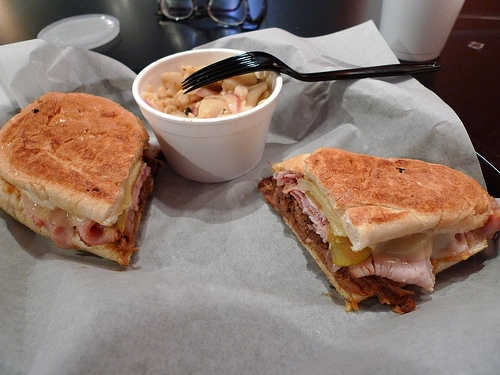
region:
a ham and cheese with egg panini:
[265, 148, 494, 325]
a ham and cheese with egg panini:
[2, 94, 159, 291]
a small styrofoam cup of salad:
[132, 43, 291, 191]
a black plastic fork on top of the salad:
[179, 43, 465, 98]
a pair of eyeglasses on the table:
[153, 0, 275, 34]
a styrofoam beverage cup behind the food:
[372, 0, 467, 71]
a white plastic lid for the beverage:
[26, 12, 130, 54]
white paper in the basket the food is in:
[361, 86, 478, 156]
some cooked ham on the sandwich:
[357, 253, 442, 295]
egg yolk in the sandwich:
[327, 239, 368, 269]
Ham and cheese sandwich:
[267, 151, 499, 323]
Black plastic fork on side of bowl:
[173, 50, 498, 115]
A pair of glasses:
[151, 0, 283, 27]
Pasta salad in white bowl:
[139, 48, 269, 135]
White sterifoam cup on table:
[147, 111, 279, 188]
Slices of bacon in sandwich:
[312, 260, 420, 325]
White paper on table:
[22, 279, 369, 374]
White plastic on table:
[27, 10, 127, 55]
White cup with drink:
[375, 0, 490, 80]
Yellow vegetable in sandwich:
[321, 227, 376, 278]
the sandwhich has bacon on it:
[280, 157, 470, 323]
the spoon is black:
[200, 35, 445, 105]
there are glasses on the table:
[160, 0, 275, 25]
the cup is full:
[140, 55, 285, 160]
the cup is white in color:
[121, 91, 293, 186]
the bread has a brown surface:
[322, 150, 483, 335]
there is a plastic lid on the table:
[50, 2, 150, 62]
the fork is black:
[186, 47, 426, 98]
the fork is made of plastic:
[175, 50, 447, 100]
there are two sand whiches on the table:
[6, 101, 482, 298]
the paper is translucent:
[145, 221, 292, 322]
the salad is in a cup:
[167, 65, 238, 115]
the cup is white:
[129, 60, 304, 205]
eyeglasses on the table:
[150, 1, 292, 57]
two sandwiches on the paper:
[10, 71, 496, 299]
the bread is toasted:
[272, 154, 486, 282]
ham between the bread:
[297, 233, 454, 334]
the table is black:
[127, 30, 163, 52]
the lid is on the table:
[15, 18, 172, 69]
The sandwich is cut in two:
[2, 89, 499, 313]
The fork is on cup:
[133, 37, 443, 182]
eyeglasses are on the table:
[153, 0, 270, 30]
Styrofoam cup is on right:
[378, 0, 467, 64]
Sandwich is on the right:
[257, 147, 499, 317]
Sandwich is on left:
[1, 92, 164, 267]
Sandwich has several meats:
[250, 150, 496, 311]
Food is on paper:
[1, 19, 499, 374]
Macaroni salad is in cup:
[131, 47, 283, 183]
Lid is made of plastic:
[34, 8, 119, 57]